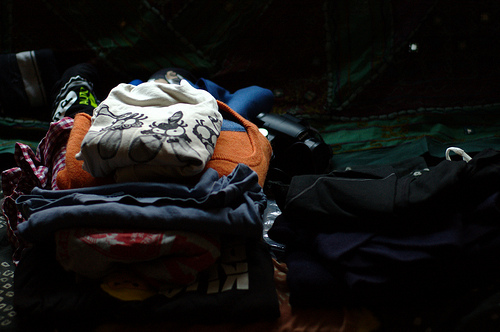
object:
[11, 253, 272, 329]
shirt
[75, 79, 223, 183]
shirt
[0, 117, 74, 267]
shirt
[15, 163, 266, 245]
towel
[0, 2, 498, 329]
room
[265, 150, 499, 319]
shirt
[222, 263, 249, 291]
letter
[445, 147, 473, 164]
string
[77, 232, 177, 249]
design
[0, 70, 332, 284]
pile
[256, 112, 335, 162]
camera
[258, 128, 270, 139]
bottle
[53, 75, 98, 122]
design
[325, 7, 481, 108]
bag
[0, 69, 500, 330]
cloth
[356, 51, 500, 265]
right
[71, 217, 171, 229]
edge